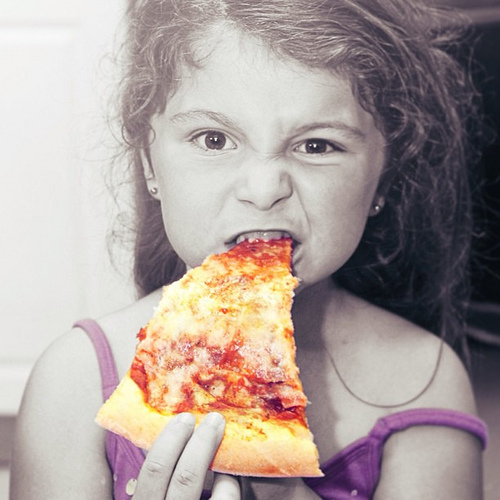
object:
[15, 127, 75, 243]
wall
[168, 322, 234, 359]
cheese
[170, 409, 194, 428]
fingernail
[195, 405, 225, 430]
fingernail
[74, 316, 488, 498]
dress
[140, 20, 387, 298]
face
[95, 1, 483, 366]
hair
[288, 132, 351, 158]
eye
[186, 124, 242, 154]
eye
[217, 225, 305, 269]
mouth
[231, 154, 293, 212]
nose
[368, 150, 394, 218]
ear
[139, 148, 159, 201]
ear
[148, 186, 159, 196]
earring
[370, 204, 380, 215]
earring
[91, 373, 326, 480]
crust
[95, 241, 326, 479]
pizza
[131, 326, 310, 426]
sauce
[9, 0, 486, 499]
child